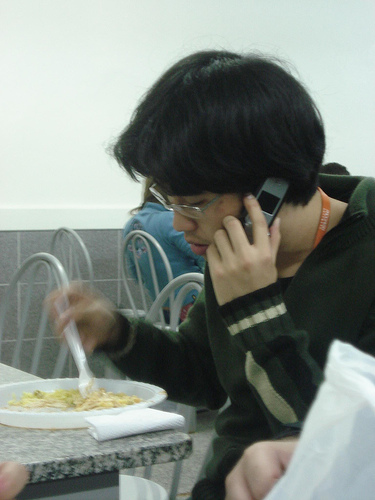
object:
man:
[46, 48, 374, 498]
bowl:
[0, 375, 167, 427]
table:
[0, 363, 194, 487]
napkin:
[88, 405, 186, 438]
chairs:
[130, 270, 212, 380]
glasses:
[149, 181, 222, 221]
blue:
[10, 64, 80, 167]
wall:
[0, 0, 375, 232]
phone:
[242, 179, 288, 254]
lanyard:
[312, 186, 331, 256]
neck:
[311, 184, 349, 261]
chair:
[1, 252, 71, 382]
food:
[4, 381, 145, 411]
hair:
[113, 51, 325, 207]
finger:
[243, 191, 268, 247]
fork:
[53, 289, 103, 404]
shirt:
[116, 174, 375, 478]